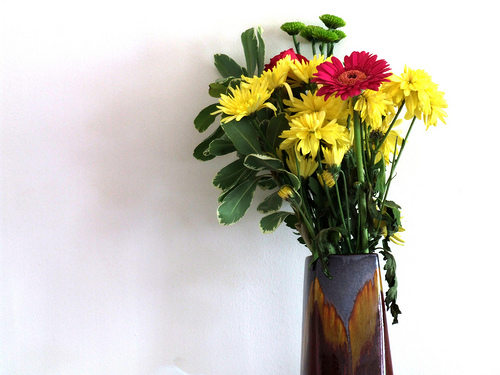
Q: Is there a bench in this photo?
A: No, there are no benches.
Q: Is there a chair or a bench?
A: No, there are no benches or chairs.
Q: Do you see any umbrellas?
A: No, there are no umbrellas.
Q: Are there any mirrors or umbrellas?
A: No, there are no umbrellas or mirrors.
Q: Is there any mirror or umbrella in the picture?
A: No, there are no umbrellas or mirrors.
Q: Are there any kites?
A: No, there are no kites.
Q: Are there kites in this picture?
A: No, there are no kites.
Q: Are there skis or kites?
A: No, there are no kites or skis.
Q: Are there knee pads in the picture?
A: No, there are no knee pads.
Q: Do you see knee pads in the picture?
A: No, there are no knee pads.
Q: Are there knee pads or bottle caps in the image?
A: No, there are no knee pads or bottle caps.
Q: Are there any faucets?
A: No, there are no faucets.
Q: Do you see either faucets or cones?
A: No, there are no faucets or cones.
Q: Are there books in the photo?
A: No, there are no books.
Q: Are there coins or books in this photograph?
A: No, there are no books or coins.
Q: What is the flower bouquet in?
A: The flower bouquet is in the vase.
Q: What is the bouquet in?
A: The flower bouquet is in the vase.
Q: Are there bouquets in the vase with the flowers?
A: Yes, there is a bouquet in the vase.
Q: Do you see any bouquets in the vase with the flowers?
A: Yes, there is a bouquet in the vase.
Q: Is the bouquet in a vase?
A: Yes, the bouquet is in a vase.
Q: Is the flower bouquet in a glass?
A: No, the flower bouquet is in a vase.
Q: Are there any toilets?
A: No, there are no toilets.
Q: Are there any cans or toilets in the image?
A: No, there are no toilets or cans.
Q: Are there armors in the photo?
A: No, there are no armors.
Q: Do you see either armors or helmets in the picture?
A: No, there are no armors or helmets.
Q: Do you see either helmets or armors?
A: No, there are no armors or helmets.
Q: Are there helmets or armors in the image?
A: No, there are no armors or helmets.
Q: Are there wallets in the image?
A: No, there are no wallets.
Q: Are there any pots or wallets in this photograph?
A: No, there are no wallets or pots.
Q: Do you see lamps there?
A: No, there are no lamps.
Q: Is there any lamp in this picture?
A: No, there are no lamps.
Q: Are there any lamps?
A: No, there are no lamps.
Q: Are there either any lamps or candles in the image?
A: No, there are no lamps or candles.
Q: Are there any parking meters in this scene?
A: No, there are no parking meters.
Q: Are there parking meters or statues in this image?
A: No, there are no parking meters or statues.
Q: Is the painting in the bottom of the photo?
A: Yes, the painting is in the bottom of the image.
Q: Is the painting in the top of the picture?
A: No, the painting is in the bottom of the image.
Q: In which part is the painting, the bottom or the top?
A: The painting is in the bottom of the image.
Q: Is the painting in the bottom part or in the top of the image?
A: The painting is in the bottom of the image.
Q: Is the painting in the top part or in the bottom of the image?
A: The painting is in the bottom of the image.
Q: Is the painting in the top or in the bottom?
A: The painting is in the bottom of the image.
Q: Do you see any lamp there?
A: No, there are no lamps.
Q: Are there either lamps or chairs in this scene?
A: No, there are no lamps or chairs.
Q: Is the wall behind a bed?
A: No, the wall is behind a vase.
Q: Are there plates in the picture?
A: No, there are no plates.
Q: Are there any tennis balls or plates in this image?
A: No, there are no plates or tennis balls.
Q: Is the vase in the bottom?
A: Yes, the vase is in the bottom of the image.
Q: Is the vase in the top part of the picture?
A: No, the vase is in the bottom of the image.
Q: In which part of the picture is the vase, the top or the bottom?
A: The vase is in the bottom of the image.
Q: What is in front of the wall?
A: The vase is in front of the wall.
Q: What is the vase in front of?
A: The vase is in front of the wall.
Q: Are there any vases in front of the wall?
A: Yes, there is a vase in front of the wall.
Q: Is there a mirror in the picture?
A: No, there are no mirrors.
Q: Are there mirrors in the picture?
A: No, there are no mirrors.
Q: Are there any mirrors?
A: No, there are no mirrors.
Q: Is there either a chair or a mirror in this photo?
A: No, there are no mirrors or chairs.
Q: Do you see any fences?
A: No, there are no fences.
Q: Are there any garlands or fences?
A: No, there are no fences or garlands.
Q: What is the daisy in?
A: The daisy is in the vase.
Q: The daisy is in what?
A: The daisy is in the vase.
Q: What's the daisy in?
A: The daisy is in the vase.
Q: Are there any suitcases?
A: No, there are no suitcases.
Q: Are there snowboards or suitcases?
A: No, there are no suitcases or snowboards.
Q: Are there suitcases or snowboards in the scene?
A: No, there are no suitcases or snowboards.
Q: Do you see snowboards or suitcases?
A: No, there are no suitcases or snowboards.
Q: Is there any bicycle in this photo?
A: No, there are no bicycles.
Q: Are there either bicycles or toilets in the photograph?
A: No, there are no bicycles or toilets.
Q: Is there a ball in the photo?
A: No, there are no balls.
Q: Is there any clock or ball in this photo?
A: No, there are no balls or clocks.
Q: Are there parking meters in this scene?
A: No, there are no parking meters.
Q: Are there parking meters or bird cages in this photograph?
A: No, there are no parking meters or bird cages.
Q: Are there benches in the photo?
A: No, there are no benches.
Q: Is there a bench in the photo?
A: No, there are no benches.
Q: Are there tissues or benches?
A: No, there are no benches or tissues.